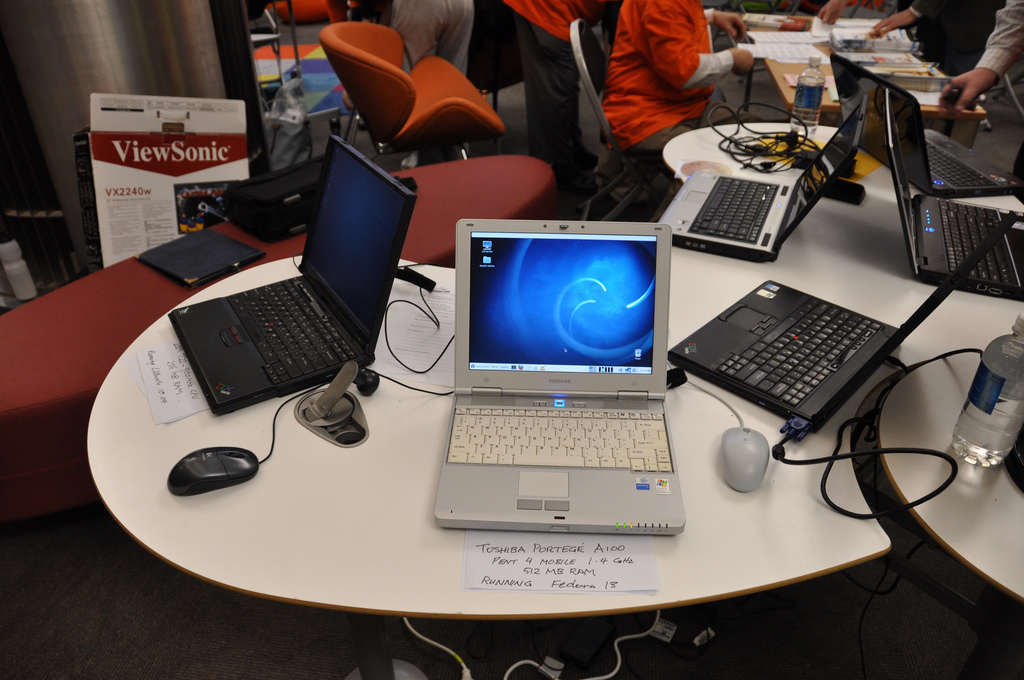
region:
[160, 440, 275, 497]
Black corded computer mouse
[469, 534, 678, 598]
Handwritten white and black note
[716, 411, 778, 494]
Corded white computer mouse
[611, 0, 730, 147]
Red and white t-shirt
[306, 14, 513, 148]
A orange computer chair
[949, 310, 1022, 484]
A full water bottle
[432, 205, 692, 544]
A white laptop computer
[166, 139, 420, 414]
A black laptop computer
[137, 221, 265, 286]
A closed black laptop computer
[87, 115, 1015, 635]
a white table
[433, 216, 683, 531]
a silver laptop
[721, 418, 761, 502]
a silver computer mouse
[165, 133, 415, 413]
a black laptop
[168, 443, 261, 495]
a black computer mouse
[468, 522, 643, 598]
a white paper on the table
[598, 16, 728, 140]
a person wearing an orange shirt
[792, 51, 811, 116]
a water bottle on the table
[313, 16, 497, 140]
an orange chair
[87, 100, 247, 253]
a white box on the ground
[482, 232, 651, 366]
blue screen on computer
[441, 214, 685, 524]
white computer on table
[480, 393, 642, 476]
white keys on computer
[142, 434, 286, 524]
black mouse on table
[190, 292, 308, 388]
black keys on computer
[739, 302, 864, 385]
black keys on computer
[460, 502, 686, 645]
white paper on table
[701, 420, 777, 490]
Computer mouse on desk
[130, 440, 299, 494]
Black mouse on desk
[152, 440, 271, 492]
Computer mouse on desk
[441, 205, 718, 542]
White computer on desk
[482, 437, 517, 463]
a button on the keyboard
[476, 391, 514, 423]
a button on the keyboard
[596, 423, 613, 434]
a button on the keyboard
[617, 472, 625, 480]
a button on the keyboard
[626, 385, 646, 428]
a button on the keyboard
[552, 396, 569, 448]
a button on the keyboard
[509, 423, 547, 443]
a button on the keyboard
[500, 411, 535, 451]
a button on the keyboard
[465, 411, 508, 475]
a button on the keyboard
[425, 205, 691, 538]
open white laptop with blue screen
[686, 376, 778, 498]
white corded computer mouse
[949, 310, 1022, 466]
plastic bottle with blue label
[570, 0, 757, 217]
sitting person wearing orange shirt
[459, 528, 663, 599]
white paper with black writing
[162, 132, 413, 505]
black laptop with black mouse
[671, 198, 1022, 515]
black laptop with black power cord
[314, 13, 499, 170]
odd shaped orange cushion chair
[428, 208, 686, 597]
white paper in front of white laptop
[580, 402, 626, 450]
a button on the keyboard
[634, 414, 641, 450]
a button on the keyboard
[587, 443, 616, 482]
a button on the keyboard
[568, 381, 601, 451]
a button on the keyboard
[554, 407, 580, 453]
a button on the keyboard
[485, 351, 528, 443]
a button on the keyboard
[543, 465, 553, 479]
a button on the keyboard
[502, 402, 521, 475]
a button on the keyboard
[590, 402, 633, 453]
a button on the keyboard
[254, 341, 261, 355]
a button on the keyboard